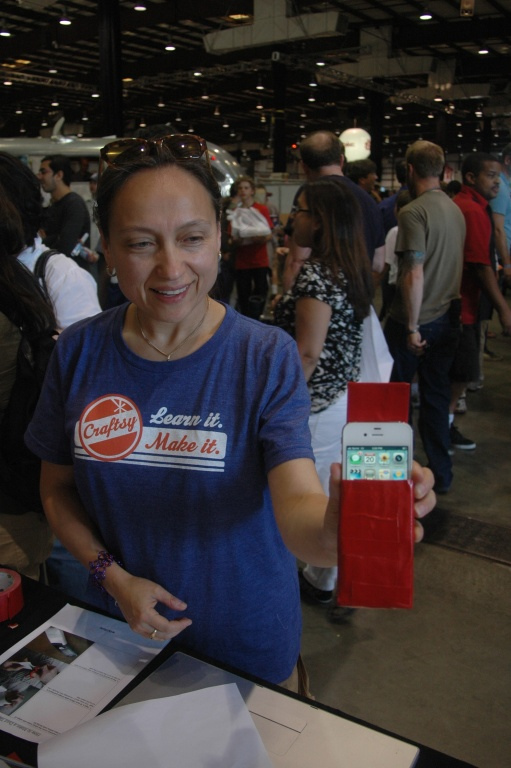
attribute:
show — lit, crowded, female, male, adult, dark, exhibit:
[132, 129, 468, 738]